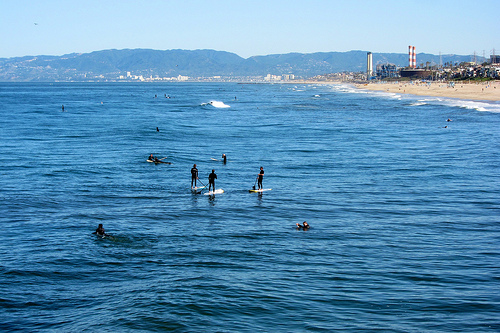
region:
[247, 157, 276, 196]
A person in the ocean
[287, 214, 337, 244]
A person in the ocean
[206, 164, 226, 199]
A person in the ocean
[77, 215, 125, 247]
A person in the ocean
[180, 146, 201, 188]
A person in the ocean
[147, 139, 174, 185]
A person in the ocean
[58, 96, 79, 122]
A person in the ocean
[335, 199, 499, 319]
A blue water surface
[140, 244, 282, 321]
A blue water surface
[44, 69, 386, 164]
A blue water surface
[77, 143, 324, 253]
A group of surfers in the ocean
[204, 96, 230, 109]
a wave in the ocean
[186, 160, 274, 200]
people paddle boarding on the water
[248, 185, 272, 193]
a board under the person's feet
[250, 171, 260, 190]
a paddle in the person's hands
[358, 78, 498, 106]
a beach with a lot of people on it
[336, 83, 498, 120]
waves forming near the shore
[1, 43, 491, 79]
a mountain range in the distance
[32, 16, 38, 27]
a plane flying through the air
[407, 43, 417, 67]
two large orange and white striped columns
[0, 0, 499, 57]
a clear blue sky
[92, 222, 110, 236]
person in the ocean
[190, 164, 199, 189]
person in the ocean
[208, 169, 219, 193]
person in the ocean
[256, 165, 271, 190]
person in the ocean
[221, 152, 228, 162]
person in the ocean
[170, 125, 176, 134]
person in the ocean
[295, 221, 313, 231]
person in the ocean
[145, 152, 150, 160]
person in the ocean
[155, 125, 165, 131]
person in the ocean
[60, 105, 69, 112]
person in the ocean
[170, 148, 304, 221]
People on mini boats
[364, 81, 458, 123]
waves washing ashore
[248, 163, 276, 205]
man on a surfboard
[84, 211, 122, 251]
person swimming in the water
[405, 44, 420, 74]
smoke stack in the distance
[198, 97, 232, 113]
waves in the ocean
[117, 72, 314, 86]
City view in the distance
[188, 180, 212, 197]
person holding a paddle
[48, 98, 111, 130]
bird in the sky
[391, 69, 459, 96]
people on the beach